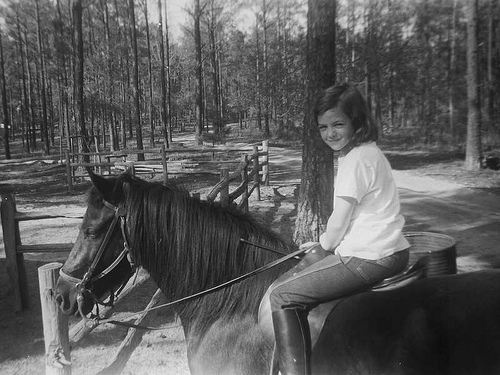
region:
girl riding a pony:
[47, 21, 436, 358]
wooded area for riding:
[39, 17, 191, 162]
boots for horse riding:
[237, 293, 334, 373]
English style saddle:
[246, 205, 430, 373]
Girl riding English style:
[215, 78, 434, 348]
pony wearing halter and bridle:
[16, 154, 185, 342]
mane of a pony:
[131, 191, 263, 333]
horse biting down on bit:
[52, 278, 126, 341]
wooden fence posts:
[80, 133, 303, 226]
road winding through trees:
[131, 75, 297, 185]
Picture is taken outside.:
[14, 12, 496, 364]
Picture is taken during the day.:
[39, 69, 414, 312]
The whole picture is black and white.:
[30, 39, 457, 342]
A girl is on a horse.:
[242, 80, 397, 374]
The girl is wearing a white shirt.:
[305, 157, 402, 259]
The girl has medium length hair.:
[279, 72, 392, 141]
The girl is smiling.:
[296, 78, 414, 199]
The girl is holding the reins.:
[236, 233, 346, 298]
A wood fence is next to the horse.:
[165, 131, 288, 195]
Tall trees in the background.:
[32, 37, 459, 143]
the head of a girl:
[311, 77, 377, 157]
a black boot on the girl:
[270, 304, 311, 374]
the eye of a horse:
[82, 222, 101, 239]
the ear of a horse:
[123, 164, 135, 179]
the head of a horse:
[44, 161, 144, 324]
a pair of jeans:
[267, 240, 409, 310]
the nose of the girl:
[324, 123, 334, 137]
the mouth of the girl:
[323, 134, 340, 146]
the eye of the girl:
[330, 117, 346, 129]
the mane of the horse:
[84, 170, 287, 335]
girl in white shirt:
[258, 80, 413, 373]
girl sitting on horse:
[264, 77, 414, 374]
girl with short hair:
[263, 80, 412, 374]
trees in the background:
[1, 0, 497, 142]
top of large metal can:
[398, 230, 457, 276]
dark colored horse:
[49, 158, 495, 373]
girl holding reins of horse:
[259, 81, 425, 373]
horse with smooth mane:
[53, 160, 299, 338]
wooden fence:
[34, 138, 285, 373]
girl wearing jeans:
[255, 78, 419, 373]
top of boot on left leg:
[268, 306, 320, 373]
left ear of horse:
[81, 163, 119, 205]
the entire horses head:
[50, 154, 146, 332]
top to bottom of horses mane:
[103, 165, 299, 330]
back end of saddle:
[362, 259, 430, 292]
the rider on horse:
[265, 76, 412, 366]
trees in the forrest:
[75, 0, 305, 132]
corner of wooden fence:
[223, 132, 278, 196]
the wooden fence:
[212, 155, 270, 207]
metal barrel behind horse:
[403, 227, 463, 276]